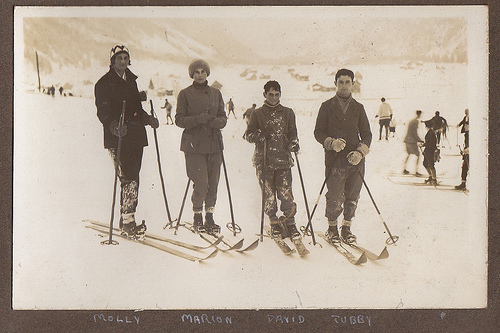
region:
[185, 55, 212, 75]
solid hat on womans head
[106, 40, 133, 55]
Zig zag designed hat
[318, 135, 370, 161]
White snow gloves on hands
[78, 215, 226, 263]
Skiis on the far left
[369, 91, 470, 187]
People skiing in the distance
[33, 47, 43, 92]
Tall post in the back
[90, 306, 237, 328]
The names Molly and Marion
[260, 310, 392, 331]
Names David and Tubby on the right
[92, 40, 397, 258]
Four people in their skii gear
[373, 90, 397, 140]
Somebody walking away with a toddler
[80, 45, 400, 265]
Four people in skiis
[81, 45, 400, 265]
Four people in skiing attire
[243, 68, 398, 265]
Two kids posing in their skiing attire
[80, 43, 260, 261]
Two skiers wearing knit hats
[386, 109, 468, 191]
A group of skiers playing on the snow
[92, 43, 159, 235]
A person wearing dark winter clothes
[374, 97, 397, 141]
A person in the background wearing a light colored top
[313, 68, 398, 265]
A young boy in skis without a hat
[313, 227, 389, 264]
A pair of skis being used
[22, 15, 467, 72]
Snowy mountains on the background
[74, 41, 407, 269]
Old time family skiing.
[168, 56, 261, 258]
Woman in fur hat on skis.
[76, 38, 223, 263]
Man with winter hat on skis, holding poles.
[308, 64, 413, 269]
Boy with gloves holding ski poles.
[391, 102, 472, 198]
Group of people skiing.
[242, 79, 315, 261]
Snow on shirt and pants of young boy.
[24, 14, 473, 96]
Mountains covered in snow with skiers.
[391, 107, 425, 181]
Woman skiing in a skirt.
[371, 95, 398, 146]
Person with a striped swear carrying bag.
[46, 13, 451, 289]
Family of skiers with mountains behind them.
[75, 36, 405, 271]
four people on skiis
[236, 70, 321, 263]
this person is leaning slightly to the right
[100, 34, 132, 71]
hat has a triangular design around the bottom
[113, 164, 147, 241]
snow is covering part of these pants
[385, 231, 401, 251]
pointy bottom of a ski pole.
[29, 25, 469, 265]
snowy mountain full of people skiing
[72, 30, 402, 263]
the people on the left are wearing hats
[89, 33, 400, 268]
people on the right are not wearing hats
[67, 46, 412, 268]
group of people are all wearing gloves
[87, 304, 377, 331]
the names of people written at the bottom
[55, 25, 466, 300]
The people are doing some skiing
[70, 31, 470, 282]
Some people are out in the snow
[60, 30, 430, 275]
Some people are out in the mountains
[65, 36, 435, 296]
Some people are getting some exercise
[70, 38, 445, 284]
Some people are using snow skis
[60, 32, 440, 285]
Some people are holding ski poles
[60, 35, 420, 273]
Some people are wearing warm clothes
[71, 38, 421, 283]
Some people are out in the daytime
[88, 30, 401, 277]
Some people are enjoying the day